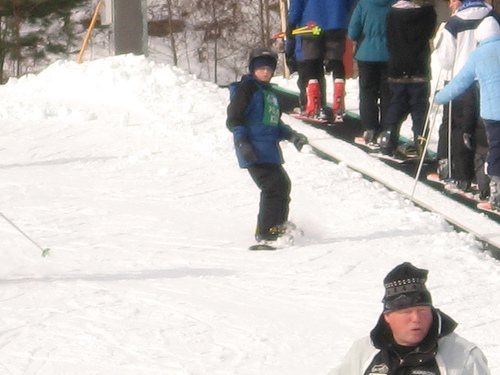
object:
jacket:
[321, 307, 488, 374]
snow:
[49, 78, 198, 135]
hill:
[0, 46, 500, 375]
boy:
[433, 14, 499, 215]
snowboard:
[248, 228, 304, 252]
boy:
[219, 42, 317, 250]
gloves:
[236, 137, 259, 165]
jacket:
[345, 0, 392, 61]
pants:
[357, 62, 387, 132]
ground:
[326, 150, 358, 200]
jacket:
[224, 73, 293, 168]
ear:
[384, 310, 394, 323]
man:
[327, 259, 498, 375]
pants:
[380, 76, 430, 148]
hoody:
[380, 0, 435, 84]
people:
[262, 0, 499, 212]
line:
[308, 112, 400, 202]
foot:
[299, 105, 324, 116]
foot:
[330, 107, 346, 123]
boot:
[301, 80, 321, 115]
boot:
[331, 82, 345, 112]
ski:
[290, 111, 327, 123]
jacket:
[430, 37, 499, 120]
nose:
[410, 311, 422, 322]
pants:
[246, 164, 290, 241]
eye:
[403, 310, 411, 314]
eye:
[418, 310, 427, 313]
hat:
[381, 261, 432, 315]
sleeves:
[233, 125, 249, 140]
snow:
[2, 326, 174, 373]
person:
[424, 0, 499, 188]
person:
[377, 0, 437, 160]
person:
[347, 0, 400, 143]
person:
[282, 0, 355, 121]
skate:
[248, 222, 304, 251]